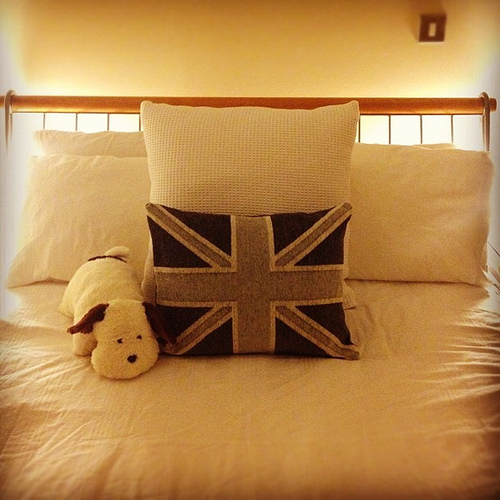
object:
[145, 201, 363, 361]
pillow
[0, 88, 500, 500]
bed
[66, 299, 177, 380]
head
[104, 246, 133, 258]
tail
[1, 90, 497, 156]
headboard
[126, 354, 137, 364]
nose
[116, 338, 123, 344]
eye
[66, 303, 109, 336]
ear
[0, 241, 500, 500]
sheet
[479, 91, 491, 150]
rod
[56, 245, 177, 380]
animal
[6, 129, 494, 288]
comforter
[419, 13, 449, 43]
switch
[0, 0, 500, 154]
wall